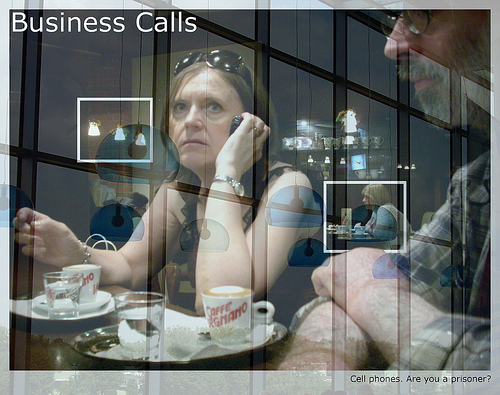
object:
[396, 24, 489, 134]
beard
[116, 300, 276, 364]
piece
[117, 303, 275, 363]
paper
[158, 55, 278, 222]
hair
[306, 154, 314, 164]
lamp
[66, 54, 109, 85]
glass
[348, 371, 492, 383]
graphic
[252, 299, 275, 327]
handle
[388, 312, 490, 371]
sleeve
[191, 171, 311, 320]
arm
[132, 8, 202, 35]
calls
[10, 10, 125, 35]
writing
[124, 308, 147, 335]
glass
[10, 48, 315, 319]
woman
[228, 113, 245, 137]
phone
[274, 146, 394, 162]
ledge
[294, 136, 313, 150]
cup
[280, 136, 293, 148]
cup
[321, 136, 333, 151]
cup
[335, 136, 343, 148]
cup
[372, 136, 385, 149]
cup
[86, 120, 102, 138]
light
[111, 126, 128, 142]
light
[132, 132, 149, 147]
light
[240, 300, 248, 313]
letter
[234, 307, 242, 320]
letter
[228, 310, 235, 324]
letter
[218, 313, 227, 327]
letter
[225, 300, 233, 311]
letter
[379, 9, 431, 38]
glasses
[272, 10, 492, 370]
man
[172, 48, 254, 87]
glasses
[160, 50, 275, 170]
head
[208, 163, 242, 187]
wrist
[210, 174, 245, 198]
watch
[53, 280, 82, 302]
glass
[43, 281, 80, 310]
water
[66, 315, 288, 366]
plate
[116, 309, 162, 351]
water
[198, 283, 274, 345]
coffee cup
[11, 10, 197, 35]
business calls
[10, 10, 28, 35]
letter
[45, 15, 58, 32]
letter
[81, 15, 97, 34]
letter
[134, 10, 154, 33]
letter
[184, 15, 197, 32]
letter